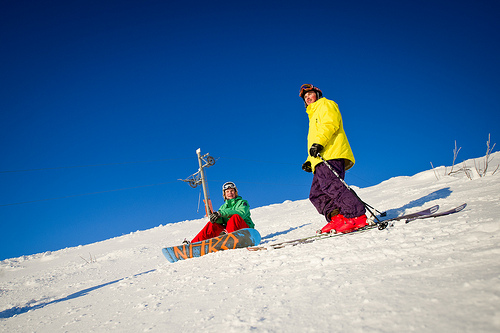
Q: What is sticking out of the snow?
A: Weeds.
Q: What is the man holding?
A: Ski poles.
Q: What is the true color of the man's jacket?
A: Yellow.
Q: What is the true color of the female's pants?
A: Red.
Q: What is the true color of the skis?
A: Gray.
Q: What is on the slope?
A: Snow.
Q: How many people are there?
A: 2.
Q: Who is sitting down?
A: The man in the green jacket.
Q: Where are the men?
A: On a hill.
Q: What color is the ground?
A: White.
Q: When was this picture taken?
A: During the day.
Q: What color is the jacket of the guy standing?
A: Yellow.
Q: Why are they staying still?
A: To take a photo.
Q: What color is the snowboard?
A: Blue.